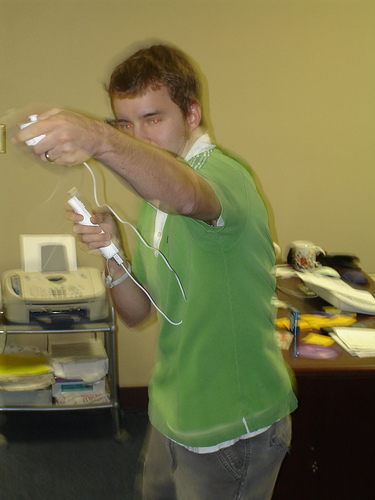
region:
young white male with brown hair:
[84, 41, 308, 486]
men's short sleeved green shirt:
[116, 148, 322, 452]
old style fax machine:
[10, 227, 106, 322]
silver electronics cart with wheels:
[4, 277, 143, 461]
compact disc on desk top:
[293, 335, 338, 366]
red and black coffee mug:
[285, 234, 325, 277]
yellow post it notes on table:
[295, 304, 353, 349]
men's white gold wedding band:
[35, 145, 58, 169]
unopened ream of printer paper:
[48, 373, 111, 398]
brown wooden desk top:
[273, 290, 373, 375]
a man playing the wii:
[11, 32, 373, 387]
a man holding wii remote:
[21, 22, 371, 414]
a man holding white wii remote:
[24, 46, 335, 366]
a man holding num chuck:
[29, 18, 356, 318]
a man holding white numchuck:
[17, 10, 356, 366]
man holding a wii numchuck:
[12, 9, 349, 340]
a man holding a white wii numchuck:
[9, 28, 270, 254]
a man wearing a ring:
[43, 72, 322, 247]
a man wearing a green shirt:
[49, 37, 362, 377]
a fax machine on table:
[9, 210, 194, 390]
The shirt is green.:
[178, 265, 279, 388]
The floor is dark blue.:
[34, 452, 134, 498]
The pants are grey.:
[143, 449, 279, 494]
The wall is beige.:
[245, 82, 374, 176]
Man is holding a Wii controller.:
[15, 111, 138, 274]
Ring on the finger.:
[30, 145, 63, 166]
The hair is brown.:
[102, 43, 206, 113]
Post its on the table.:
[276, 295, 355, 356]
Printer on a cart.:
[2, 250, 112, 321]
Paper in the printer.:
[14, 227, 87, 276]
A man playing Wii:
[20, 46, 317, 497]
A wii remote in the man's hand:
[50, 189, 128, 278]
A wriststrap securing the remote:
[99, 258, 136, 294]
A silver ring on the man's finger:
[43, 149, 55, 163]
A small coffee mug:
[293, 237, 325, 275]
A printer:
[0, 264, 118, 318]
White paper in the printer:
[20, 229, 80, 269]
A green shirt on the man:
[65, 153, 310, 447]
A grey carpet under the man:
[25, 439, 119, 496]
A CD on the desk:
[296, 335, 338, 367]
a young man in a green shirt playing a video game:
[4, 46, 315, 490]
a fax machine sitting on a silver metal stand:
[2, 234, 112, 334]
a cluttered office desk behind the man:
[272, 238, 373, 364]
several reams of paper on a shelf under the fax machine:
[42, 342, 114, 411]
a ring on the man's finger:
[42, 149, 54, 164]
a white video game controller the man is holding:
[63, 196, 124, 274]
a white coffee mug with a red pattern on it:
[291, 238, 326, 267]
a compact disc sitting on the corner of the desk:
[295, 340, 340, 363]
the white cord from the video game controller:
[132, 278, 202, 333]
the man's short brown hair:
[107, 45, 195, 99]